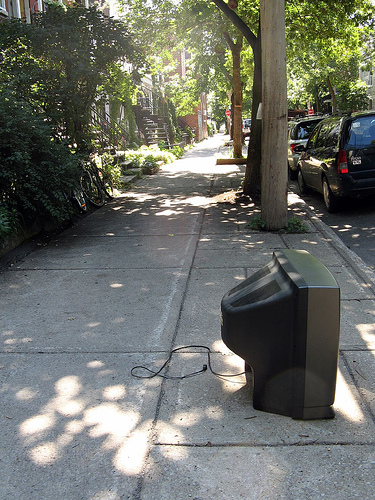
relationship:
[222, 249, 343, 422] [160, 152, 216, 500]
television on roadside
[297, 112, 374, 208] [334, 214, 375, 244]
car on road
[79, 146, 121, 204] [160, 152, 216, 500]
bicyle on roadside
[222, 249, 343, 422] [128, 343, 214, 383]
television has a cord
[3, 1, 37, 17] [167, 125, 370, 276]
house on street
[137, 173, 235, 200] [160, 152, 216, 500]
shade on sidewalk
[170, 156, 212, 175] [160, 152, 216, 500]
reflection on roadside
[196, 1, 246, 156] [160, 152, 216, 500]
tree on roadside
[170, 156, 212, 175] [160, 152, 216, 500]
sunlight on top of roadside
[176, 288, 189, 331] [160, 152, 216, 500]
crack on sidewalk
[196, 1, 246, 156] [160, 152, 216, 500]
tree on sidewalk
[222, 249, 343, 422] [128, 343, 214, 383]
television has a wire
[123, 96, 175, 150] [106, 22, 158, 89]
staircase leading to house